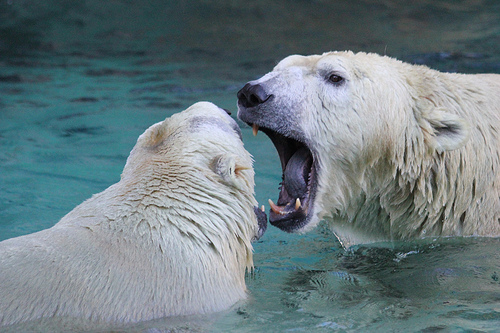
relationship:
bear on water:
[3, 102, 270, 327] [0, 1, 498, 331]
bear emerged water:
[237, 49, 499, 249] [0, 1, 498, 331]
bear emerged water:
[3, 102, 270, 327] [0, 1, 498, 331]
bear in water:
[3, 102, 270, 327] [79, 62, 150, 120]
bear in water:
[235, 49, 499, 249] [0, 1, 498, 331]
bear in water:
[3, 100, 267, 326] [0, 1, 498, 331]